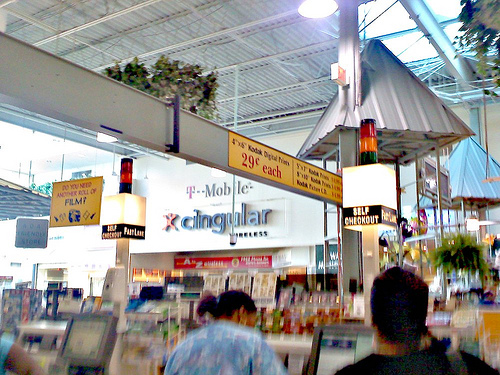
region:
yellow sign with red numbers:
[228, 131, 340, 203]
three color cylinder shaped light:
[358, 118, 378, 165]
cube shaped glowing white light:
[342, 164, 395, 230]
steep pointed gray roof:
[297, 36, 474, 164]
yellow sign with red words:
[48, 174, 101, 226]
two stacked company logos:
[162, 181, 270, 233]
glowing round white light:
[297, 0, 338, 20]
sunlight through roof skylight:
[359, 0, 464, 70]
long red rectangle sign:
[173, 255, 271, 267]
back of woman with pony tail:
[163, 290, 279, 373]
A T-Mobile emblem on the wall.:
[182, 179, 257, 199]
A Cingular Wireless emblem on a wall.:
[161, 200, 276, 243]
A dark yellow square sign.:
[46, 173, 105, 228]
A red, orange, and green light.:
[356, 117, 382, 167]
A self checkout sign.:
[342, 203, 399, 230]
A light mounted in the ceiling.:
[296, 0, 345, 22]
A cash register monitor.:
[56, 312, 119, 372]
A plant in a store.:
[428, 231, 494, 291]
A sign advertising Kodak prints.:
[224, 128, 345, 205]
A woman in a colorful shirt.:
[161, 288, 292, 373]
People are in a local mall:
[8, 18, 488, 359]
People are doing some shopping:
[6, 21, 491, 359]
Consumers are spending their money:
[6, 31, 487, 361]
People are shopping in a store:
[3, 20, 484, 367]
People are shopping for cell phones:
[3, 7, 495, 372]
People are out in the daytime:
[3, 18, 489, 366]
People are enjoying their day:
[11, 36, 486, 362]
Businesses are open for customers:
[5, 28, 490, 358]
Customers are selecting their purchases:
[10, 27, 496, 363]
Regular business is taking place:
[10, 25, 492, 368]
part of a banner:
[268, 150, 303, 183]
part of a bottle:
[313, 275, 330, 310]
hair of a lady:
[228, 290, 241, 303]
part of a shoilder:
[224, 305, 256, 350]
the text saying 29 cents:
[237, 142, 263, 172]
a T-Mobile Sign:
[179, 176, 269, 203]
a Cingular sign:
[164, 211, 275, 232]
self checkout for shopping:
[341, 198, 392, 232]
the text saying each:
[256, 161, 293, 182]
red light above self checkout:
[359, 115, 384, 140]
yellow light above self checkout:
[353, 137, 388, 155]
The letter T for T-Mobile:
[180, 182, 200, 205]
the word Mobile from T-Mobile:
[199, 178, 254, 200]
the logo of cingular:
[156, 205, 178, 235]